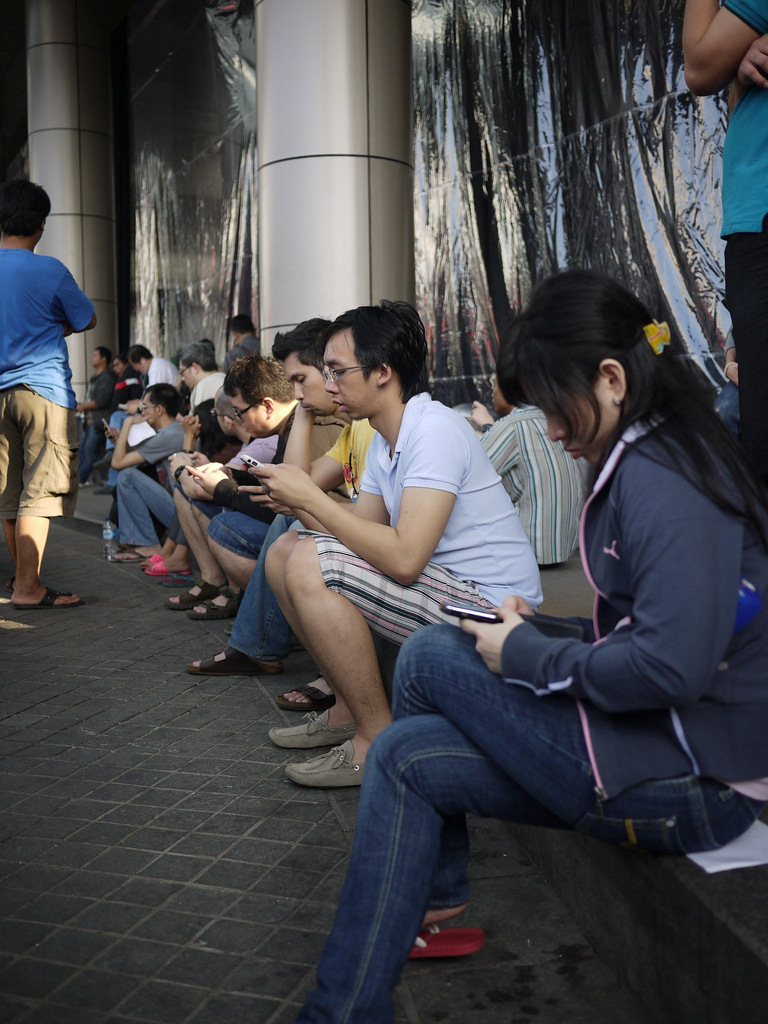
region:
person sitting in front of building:
[109, 383, 198, 566]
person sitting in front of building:
[140, 397, 244, 580]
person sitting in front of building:
[177, 314, 369, 705]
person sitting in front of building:
[482, 332, 591, 571]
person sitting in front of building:
[235, 298, 545, 787]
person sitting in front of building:
[289, 267, 762, 1019]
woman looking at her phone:
[294, 268, 764, 1022]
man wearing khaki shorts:
[0, 174, 93, 611]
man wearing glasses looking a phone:
[231, 295, 544, 792]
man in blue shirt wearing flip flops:
[1, 177, 92, 613]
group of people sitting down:
[105, 266, 763, 1023]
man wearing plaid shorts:
[238, 291, 547, 795]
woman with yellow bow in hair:
[299, 266, 761, 1021]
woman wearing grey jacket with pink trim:
[286, 266, 763, 1021]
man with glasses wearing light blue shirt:
[241, 301, 548, 792]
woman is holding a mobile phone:
[324, 271, 763, 1022]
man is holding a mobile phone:
[234, 300, 539, 790]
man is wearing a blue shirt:
[1, 239, 94, 407]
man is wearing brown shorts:
[6, 388, 82, 517]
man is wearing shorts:
[293, 514, 528, 650]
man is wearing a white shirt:
[356, 392, 552, 615]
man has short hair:
[325, 300, 441, 398]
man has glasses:
[315, 357, 379, 384]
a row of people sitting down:
[119, 354, 648, 806]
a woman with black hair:
[508, 284, 662, 467]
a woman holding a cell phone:
[442, 589, 536, 639]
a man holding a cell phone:
[239, 451, 296, 503]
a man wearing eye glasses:
[320, 344, 356, 397]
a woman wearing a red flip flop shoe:
[397, 906, 488, 963]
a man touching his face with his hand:
[119, 392, 169, 438]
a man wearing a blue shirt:
[2, 239, 63, 415]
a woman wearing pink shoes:
[140, 547, 183, 582]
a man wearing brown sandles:
[11, 581, 83, 616]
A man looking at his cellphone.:
[248, 322, 571, 877]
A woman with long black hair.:
[358, 265, 766, 954]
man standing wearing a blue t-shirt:
[0, 179, 92, 615]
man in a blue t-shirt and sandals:
[2, 180, 98, 612]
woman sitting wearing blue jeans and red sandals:
[348, 272, 766, 1022]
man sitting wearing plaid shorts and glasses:
[324, 297, 545, 644]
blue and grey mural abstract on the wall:
[75, 0, 681, 273]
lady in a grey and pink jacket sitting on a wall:
[488, 265, 766, 851]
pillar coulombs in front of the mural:
[255, 2, 423, 301]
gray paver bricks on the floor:
[1, 670, 265, 1022]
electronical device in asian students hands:
[441, 596, 501, 622]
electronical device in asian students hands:
[238, 451, 257, 469]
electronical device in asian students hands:
[95, 416, 112, 430]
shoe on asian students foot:
[283, 734, 383, 787]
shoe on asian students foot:
[266, 710, 361, 748]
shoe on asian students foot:
[276, 677, 342, 715]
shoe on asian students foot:
[184, 583, 245, 624]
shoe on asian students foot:
[164, 581, 227, 616]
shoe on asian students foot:
[9, 580, 85, 612]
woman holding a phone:
[405, 558, 587, 709]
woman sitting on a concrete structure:
[199, 249, 749, 1017]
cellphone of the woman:
[426, 580, 506, 627]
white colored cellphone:
[228, 448, 280, 477]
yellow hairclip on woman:
[631, 306, 670, 352]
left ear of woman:
[585, 339, 638, 417]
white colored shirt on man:
[357, 391, 529, 606]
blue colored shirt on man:
[5, 246, 91, 407]